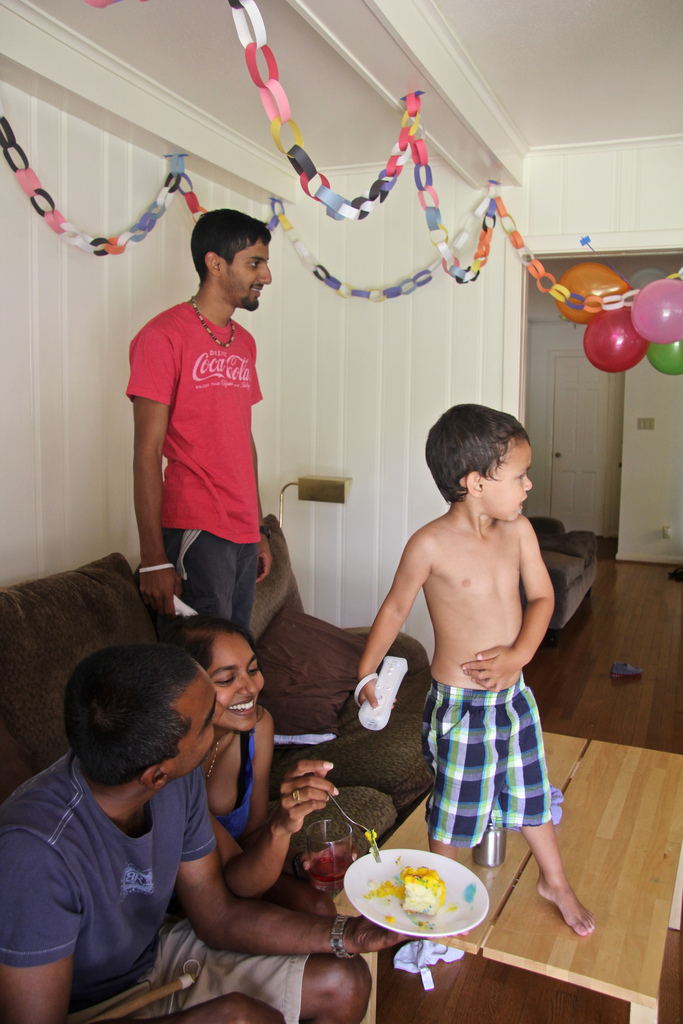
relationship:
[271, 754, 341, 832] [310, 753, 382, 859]
hand holding fork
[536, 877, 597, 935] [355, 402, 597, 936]
foot of boy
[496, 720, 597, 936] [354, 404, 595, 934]
leg of person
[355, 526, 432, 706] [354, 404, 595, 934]
arm of person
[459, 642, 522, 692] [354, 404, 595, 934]
hand of person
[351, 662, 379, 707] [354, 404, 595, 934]
hand of person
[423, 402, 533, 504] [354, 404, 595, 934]
hair of person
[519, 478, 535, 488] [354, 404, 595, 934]
nose of person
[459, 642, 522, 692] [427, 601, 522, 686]
hand on belly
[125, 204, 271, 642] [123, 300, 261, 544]
man wearing t-shirt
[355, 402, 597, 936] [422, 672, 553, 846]
boy wearing shorts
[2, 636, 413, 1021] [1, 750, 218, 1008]
man wearing t-shirt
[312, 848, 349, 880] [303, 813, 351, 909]
liquid inside a glass